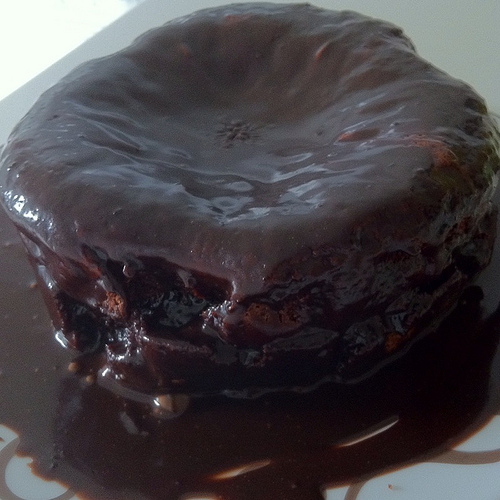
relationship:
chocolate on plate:
[65, 140, 399, 480] [23, 420, 411, 477]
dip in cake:
[61, 236, 224, 386] [0, 13, 461, 444]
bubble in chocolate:
[131, 369, 203, 411] [57, 115, 410, 336]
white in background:
[24, 6, 88, 60] [32, 6, 182, 36]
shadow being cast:
[84, 25, 151, 84] [97, 16, 269, 66]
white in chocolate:
[300, 406, 415, 464] [185, 304, 453, 428]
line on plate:
[331, 405, 481, 498] [197, 360, 451, 478]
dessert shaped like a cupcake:
[8, 5, 462, 467] [49, 49, 485, 440]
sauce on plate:
[31, 414, 402, 498] [183, 380, 452, 483]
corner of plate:
[401, 439, 497, 495] [187, 389, 438, 493]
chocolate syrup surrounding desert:
[3, 235, 482, 496] [7, 1, 471, 418]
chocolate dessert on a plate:
[8, 5, 483, 389] [4, 4, 499, 496]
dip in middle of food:
[174, 52, 314, 172] [4, 0, 484, 424]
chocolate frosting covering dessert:
[6, 6, 484, 295] [5, 4, 480, 417]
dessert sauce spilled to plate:
[37, 392, 269, 466] [2, 388, 462, 496]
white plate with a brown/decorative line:
[387, 463, 470, 498] [427, 450, 481, 460]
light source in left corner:
[9, 5, 59, 35] [5, 0, 86, 65]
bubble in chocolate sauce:
[24, 276, 43, 289] [0, 274, 126, 498]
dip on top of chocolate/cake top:
[168, 54, 309, 170] [6, 0, 478, 286]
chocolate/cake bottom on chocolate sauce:
[73, 336, 373, 395] [25, 398, 301, 498]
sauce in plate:
[1, 330, 482, 498] [201, 411, 417, 486]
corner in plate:
[125, 4, 497, 124] [4, 4, 499, 496]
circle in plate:
[2, 422, 87, 497] [4, 4, 499, 496]